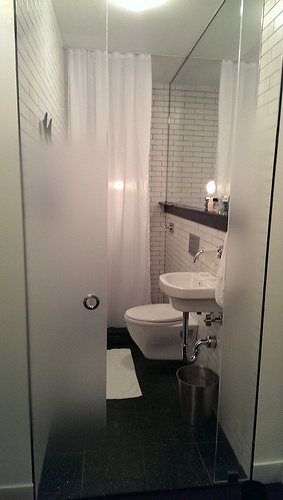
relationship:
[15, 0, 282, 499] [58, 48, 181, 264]
mirror in bathroom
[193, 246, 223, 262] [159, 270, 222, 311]
faucet on top of sink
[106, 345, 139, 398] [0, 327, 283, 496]
towel on floor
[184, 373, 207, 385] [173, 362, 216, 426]
trash in bin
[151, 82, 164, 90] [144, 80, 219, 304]
tile on wall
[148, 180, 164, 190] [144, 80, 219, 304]
tile on wall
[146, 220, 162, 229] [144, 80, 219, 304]
tile on wall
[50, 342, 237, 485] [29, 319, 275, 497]
tiles on floor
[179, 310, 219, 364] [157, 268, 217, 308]
pipe under sink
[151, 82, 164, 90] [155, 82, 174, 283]
tile on wall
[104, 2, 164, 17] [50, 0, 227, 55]
light on ceiling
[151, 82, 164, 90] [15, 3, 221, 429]
tile in bathroom